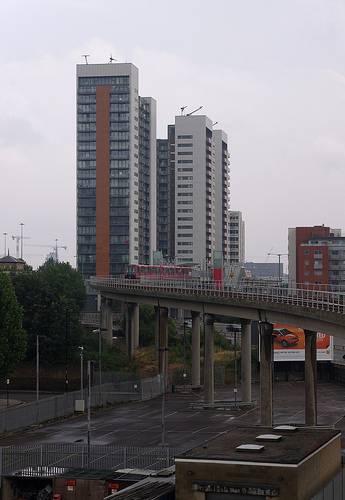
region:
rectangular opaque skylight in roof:
[234, 441, 265, 453]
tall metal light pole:
[158, 344, 166, 445]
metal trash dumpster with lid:
[56, 467, 110, 497]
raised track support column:
[203, 315, 214, 408]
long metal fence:
[1, 443, 175, 470]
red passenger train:
[125, 264, 193, 282]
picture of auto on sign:
[272, 327, 298, 347]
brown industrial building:
[174, 425, 340, 496]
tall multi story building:
[77, 62, 138, 272]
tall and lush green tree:
[37, 260, 81, 367]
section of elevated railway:
[90, 274, 343, 415]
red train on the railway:
[119, 258, 208, 286]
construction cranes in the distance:
[4, 218, 76, 272]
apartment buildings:
[285, 221, 344, 301]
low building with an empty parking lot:
[4, 386, 344, 496]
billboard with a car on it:
[253, 316, 337, 358]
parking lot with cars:
[183, 312, 271, 357]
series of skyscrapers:
[66, 45, 249, 263]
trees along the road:
[1, 265, 86, 392]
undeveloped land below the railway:
[124, 327, 247, 376]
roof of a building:
[233, 444, 238, 449]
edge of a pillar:
[205, 388, 206, 404]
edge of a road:
[296, 331, 297, 348]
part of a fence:
[121, 447, 144, 456]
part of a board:
[291, 337, 297, 346]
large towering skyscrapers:
[65, 48, 259, 347]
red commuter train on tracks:
[113, 254, 209, 288]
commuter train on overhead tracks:
[84, 259, 341, 406]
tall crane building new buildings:
[9, 223, 71, 277]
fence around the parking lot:
[8, 367, 165, 470]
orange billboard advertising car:
[263, 318, 328, 365]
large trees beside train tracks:
[6, 262, 112, 383]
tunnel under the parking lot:
[7, 476, 124, 498]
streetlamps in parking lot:
[40, 314, 190, 444]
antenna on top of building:
[80, 39, 121, 69]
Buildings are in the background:
[68, 58, 254, 268]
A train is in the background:
[121, 256, 200, 288]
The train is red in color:
[120, 259, 195, 284]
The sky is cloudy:
[4, 4, 343, 212]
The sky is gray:
[4, 6, 344, 195]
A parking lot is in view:
[62, 380, 342, 461]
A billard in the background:
[255, 315, 334, 365]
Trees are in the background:
[2, 255, 93, 387]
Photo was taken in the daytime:
[9, 8, 344, 493]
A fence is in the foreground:
[2, 441, 185, 474]